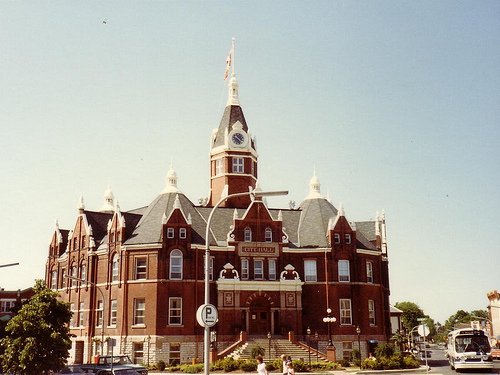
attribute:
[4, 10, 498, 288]
sky — clear, cloudless, blue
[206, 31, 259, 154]
steeple — white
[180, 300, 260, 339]
sign — parking sign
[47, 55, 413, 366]
building — red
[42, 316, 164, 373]
truck — blue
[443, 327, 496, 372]
bus — white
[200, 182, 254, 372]
pole — light pole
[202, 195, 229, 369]
pole — metal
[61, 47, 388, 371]
building — red